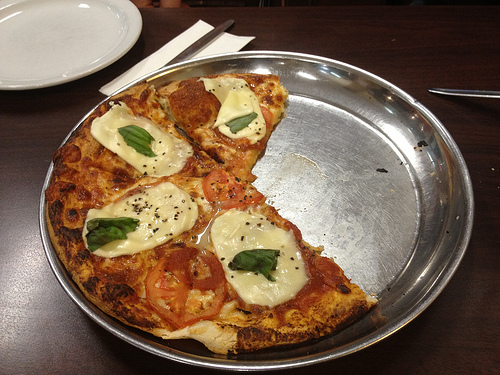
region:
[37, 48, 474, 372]
The plate is round.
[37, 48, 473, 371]
The plate is gray.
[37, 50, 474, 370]
The plate is made of metal.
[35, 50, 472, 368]
The pizza is on a plate.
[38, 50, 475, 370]
The pizza has slices missing.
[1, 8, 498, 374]
The plate is on a wood table.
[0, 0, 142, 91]
The plate is white.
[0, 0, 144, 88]
The plate is made of glass.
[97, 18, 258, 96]
The napkin is made of paper.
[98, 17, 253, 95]
The napkin is white.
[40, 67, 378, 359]
a cooked pizza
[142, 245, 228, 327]
a slice of red tomato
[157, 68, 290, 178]
a cut slice of pizza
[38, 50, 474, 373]
pizza on a silver serving dish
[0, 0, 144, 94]
a empty white plate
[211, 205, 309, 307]
a slice of mozzarella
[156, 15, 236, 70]
a silver utensil on napkin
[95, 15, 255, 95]
a white napkin under silver utensil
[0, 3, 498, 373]
a dark brown wooden table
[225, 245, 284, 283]
a green basil leaf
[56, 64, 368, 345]
partially eaten pizza in silver pan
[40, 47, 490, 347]
silver pizza pan on table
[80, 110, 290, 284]
green seasonings on pizza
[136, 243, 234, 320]
slice of tomato on pizza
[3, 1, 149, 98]
white plate sitting on table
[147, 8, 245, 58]
knife sitting on white napkin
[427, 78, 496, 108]
handle on silverware on right side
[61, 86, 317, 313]
cheese on pizza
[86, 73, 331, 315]
toppings on the partially eaten pizza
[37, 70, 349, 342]
crust of partially eaten pizza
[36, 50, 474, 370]
round silver tray on table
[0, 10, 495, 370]
dark brown table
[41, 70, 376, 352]
sliced pizza on tray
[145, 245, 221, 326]
red round tomato on pizza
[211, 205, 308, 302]
white cheese on pizza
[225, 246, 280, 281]
green herb on cheese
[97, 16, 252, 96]
white napkin next to tray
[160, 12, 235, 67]
silver utensil on napkin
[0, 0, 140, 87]
round white ceramic plate next to napkin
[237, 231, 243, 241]
black pepper sprinkle on cheese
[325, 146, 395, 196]
the pan is silver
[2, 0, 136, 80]
the plate is white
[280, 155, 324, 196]
the grease is on the pan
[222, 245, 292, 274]
the garnish is on the pizza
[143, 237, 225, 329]
the tomato is red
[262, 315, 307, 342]
the crust is brown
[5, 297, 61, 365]
the table is dark brown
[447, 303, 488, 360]
the table is wooden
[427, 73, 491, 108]
the knife is dull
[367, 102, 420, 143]
the pan is shiney